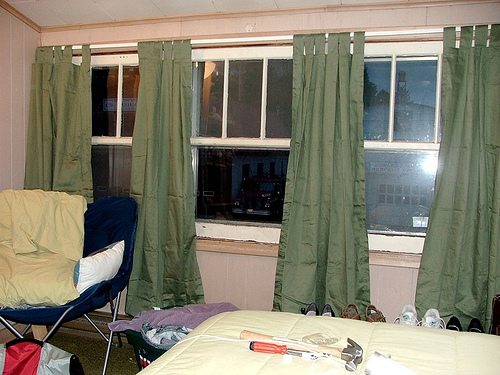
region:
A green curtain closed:
[127, 43, 202, 315]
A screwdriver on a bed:
[247, 342, 316, 359]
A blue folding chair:
[0, 195, 140, 372]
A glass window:
[192, 59, 224, 139]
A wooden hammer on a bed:
[240, 329, 360, 369]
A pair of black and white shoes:
[300, 300, 337, 316]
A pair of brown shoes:
[342, 302, 387, 322]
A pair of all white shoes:
[392, 303, 443, 328]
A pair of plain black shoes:
[445, 313, 485, 333]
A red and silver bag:
[0, 338, 85, 373]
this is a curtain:
[298, 45, 369, 344]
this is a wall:
[7, 17, 28, 157]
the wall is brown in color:
[5, 25, 30, 97]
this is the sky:
[411, 68, 434, 97]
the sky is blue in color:
[414, 68, 429, 89]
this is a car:
[227, 176, 278, 217]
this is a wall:
[231, 162, 259, 174]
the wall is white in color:
[231, 160, 241, 179]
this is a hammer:
[304, 345, 368, 366]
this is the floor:
[75, 331, 107, 351]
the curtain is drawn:
[110, 29, 232, 333]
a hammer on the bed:
[214, 305, 364, 371]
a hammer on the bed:
[239, 325, 351, 369]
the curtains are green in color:
[141, 96, 193, 237]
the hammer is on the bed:
[251, 316, 371, 364]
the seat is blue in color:
[101, 201, 138, 231]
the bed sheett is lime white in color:
[412, 321, 446, 371]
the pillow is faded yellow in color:
[28, 217, 66, 279]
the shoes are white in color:
[398, 301, 430, 331]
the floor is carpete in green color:
[89, 335, 126, 372]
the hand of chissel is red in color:
[243, 330, 290, 367]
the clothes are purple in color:
[173, 293, 208, 334]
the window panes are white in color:
[206, 45, 286, 147]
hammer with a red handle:
[249, 335, 363, 369]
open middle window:
[197, 145, 284, 222]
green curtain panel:
[127, 38, 204, 310]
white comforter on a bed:
[133, 308, 498, 373]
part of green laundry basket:
[125, 330, 162, 367]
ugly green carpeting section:
[5, 333, 137, 373]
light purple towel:
[106, 298, 234, 331]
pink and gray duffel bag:
[1, 340, 83, 374]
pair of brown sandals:
[340, 302, 385, 323]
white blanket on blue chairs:
[1, 188, 86, 302]